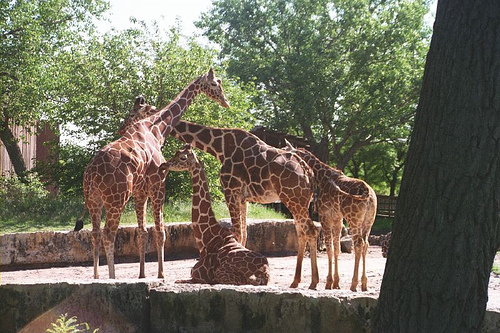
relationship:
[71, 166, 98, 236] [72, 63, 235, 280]
tail of giraffe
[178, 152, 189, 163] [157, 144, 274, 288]
eye of giraffe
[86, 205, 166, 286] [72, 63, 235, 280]
legs of giraffe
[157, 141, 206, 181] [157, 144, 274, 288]
head of giraffe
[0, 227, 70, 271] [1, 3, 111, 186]
wall near tree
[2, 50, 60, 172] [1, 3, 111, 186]
branch on tree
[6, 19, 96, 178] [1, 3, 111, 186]
branch on tree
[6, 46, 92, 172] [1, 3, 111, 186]
branch on tree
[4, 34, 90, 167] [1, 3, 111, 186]
branch on tree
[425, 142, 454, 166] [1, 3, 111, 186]
bark on side of tree